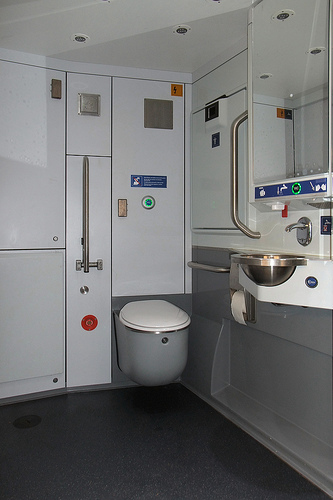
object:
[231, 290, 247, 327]
toilet pape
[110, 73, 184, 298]
wall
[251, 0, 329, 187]
mirror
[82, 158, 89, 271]
handle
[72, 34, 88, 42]
ceiling lights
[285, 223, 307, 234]
faucet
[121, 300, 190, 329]
lid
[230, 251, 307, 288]
sink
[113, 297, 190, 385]
toilet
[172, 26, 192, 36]
lights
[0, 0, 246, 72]
ceiling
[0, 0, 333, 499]
bathroom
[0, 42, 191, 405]
building